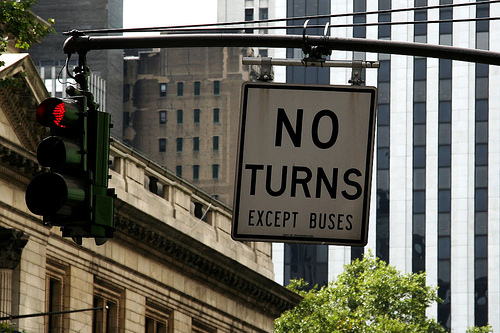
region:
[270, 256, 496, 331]
tree sitting in front of building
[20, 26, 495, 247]
traffic light affixed to pole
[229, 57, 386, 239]
street sign hanging from pole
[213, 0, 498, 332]
tall white building in background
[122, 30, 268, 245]
tall brown building sitting near white building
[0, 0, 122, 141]
tall gray building next to brown building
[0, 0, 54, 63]
tall tree near tall building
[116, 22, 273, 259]
brown old looking building in distance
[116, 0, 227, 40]
white clear looking sky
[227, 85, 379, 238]
street sign with rust hanging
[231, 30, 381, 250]
large sign is hanging from a pole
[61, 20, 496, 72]
pole hangs out over head in street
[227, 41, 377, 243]
white and black sign displays road rules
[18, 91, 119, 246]
traffic light displays a red light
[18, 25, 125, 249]
stop light is painted jet black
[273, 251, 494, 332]
large tall tree in the bottom of photo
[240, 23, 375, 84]
holds up sign on pole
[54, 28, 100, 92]
this is where the stoplight is attached to pole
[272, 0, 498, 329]
large building with black windows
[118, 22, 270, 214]
older weathered building in the distance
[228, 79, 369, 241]
this is a post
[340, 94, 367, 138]
the post is grey in color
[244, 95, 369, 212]
it is written no turns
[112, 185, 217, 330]
this is the building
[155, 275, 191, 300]
the walls are old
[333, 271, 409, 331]
the leaves are green n color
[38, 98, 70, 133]
the light is on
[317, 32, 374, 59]
this is a pole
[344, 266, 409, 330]
the leaves are bright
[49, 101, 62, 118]
the light is red in color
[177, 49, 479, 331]
This is a sign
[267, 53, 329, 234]
The sign is square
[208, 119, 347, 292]
The sign says No Turns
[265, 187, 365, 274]
The sign is white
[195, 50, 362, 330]
The border is black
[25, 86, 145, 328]
This is a street light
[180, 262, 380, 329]
This is an old tree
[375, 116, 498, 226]
This is a tall building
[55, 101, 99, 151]
The light is red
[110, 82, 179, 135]
This is a window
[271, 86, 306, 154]
part of a letter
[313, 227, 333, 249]
part of a board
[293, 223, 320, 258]
dge of a bord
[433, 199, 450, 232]
part of a window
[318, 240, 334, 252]
edge of a board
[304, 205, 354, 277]
part oof a board